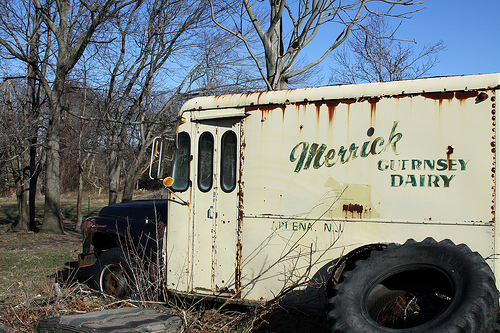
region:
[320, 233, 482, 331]
A old tire leaning on truck.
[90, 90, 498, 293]
A old dairy truck.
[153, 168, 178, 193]
A orange reflector.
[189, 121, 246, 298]
Doors on side of truck.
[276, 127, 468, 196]
Green writing on side of truck.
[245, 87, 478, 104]
Rust on old truck.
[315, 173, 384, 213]
Cow shape on side of truck.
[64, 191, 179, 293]
Black paint on front of truck.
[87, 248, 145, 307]
Tire on driver side of truck.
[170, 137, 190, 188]
Windshield on front of truck.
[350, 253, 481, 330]
a tire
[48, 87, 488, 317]
a truck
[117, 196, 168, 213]
the hood of the truck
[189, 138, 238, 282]
the door on the truck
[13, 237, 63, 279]
the green grass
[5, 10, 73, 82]
tree branches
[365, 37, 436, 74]
the long tree branches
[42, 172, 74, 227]
a tree trunk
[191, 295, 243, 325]
tree branches in a pile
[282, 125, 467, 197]
a green logo on the truck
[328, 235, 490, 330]
Big tire leaning on truck.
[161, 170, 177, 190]
Orange light reflector.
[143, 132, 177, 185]
Driver side mirrors on truck.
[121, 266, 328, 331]
Dead branches beside truck.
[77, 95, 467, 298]
Old diary delivery truck.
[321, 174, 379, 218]
Cow shape on truck.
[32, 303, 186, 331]
Old gray cushion on ground.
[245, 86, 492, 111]
Rust on top of truck.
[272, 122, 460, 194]
Green painted label on side of truck.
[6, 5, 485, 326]
an old dairy truck sitting in a wooded area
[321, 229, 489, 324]
an old truck tire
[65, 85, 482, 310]
an antique dairy truck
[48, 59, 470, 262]
an old Merrick Dairy truck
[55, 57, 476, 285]
an antique truck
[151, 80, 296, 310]
doors on an old truck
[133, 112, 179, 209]
the side mirrors on an old truck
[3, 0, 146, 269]
deciduous trees with no foliage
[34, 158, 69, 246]
tree trunk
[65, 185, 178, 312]
the black hood of an old truck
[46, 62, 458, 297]
old truck abandoned near woods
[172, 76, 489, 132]
top of old milk truck is rusted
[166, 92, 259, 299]
doorway to milk truck is rusted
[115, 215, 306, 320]
weeds are growing by the old truck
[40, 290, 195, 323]
large grey rock by the truck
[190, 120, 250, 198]
two windows in the doorway to the truck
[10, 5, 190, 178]
trees in the background have no leaves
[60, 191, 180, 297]
front end of truck is black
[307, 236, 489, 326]
large tire is on it's side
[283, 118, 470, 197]
green lettering is faded